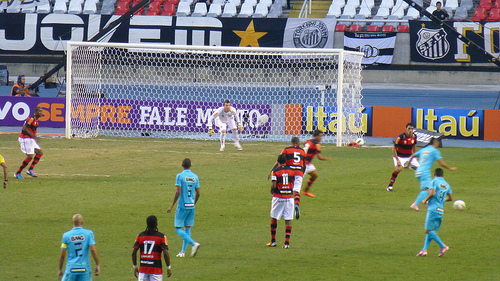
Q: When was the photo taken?
A: Daytime.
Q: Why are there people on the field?
A: They're playing soccer.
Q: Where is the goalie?
A: In the goal.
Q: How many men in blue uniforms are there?
A: Four.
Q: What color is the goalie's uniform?
A: White.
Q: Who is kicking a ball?
A: The man in blue on the right.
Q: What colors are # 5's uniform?
A: Black and red.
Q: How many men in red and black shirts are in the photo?
A: Six.